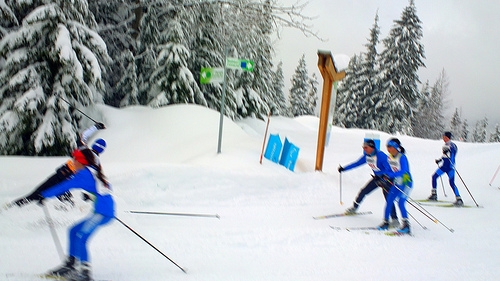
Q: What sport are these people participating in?
A: Skiing.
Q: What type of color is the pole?
A: Brown.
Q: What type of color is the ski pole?
A: Black.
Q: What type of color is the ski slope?
A: White.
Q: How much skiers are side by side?
A: 1.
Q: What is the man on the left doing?
A: Falling down.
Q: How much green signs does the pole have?
A: 2.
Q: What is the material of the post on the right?
A: Wood.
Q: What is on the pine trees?
A: Snow.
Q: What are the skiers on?
A: Cross country.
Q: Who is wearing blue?
A: The skiers.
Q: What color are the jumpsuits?
A: Blue.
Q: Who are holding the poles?
A: The skiers.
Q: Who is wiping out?
A: The skier.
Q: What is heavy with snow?
A: The trees.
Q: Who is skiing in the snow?
A: The people.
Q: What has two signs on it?
A: A pole.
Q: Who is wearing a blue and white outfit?
A: A woman.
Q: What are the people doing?
A: Skiing.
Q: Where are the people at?
A: Ski slope.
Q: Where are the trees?
A: Near green signs.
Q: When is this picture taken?
A: Winter.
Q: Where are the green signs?
A: Grey pole.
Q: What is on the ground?
A: Snow.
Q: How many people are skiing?
A: Five.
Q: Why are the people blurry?
A: They are moving fast.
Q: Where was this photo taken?
A: On a ski slope.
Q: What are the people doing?
A: Skiing.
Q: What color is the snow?
A: White.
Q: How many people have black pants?
A: Two.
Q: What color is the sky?
A: Gray.